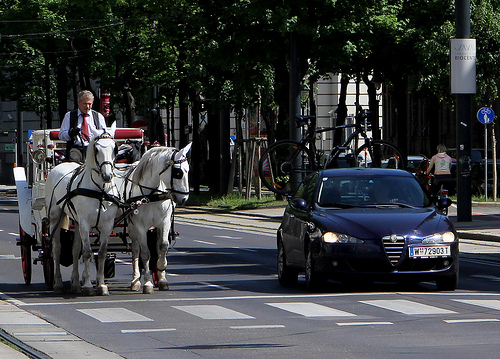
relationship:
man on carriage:
[59, 90, 110, 167] [18, 113, 152, 233]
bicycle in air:
[257, 101, 408, 197] [226, 148, 264, 235]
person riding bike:
[420, 145, 459, 199] [421, 172, 459, 214]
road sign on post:
[476, 113, 484, 124] [474, 105, 498, 202]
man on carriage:
[59, 90, 110, 167] [29, 128, 233, 295]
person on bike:
[420, 145, 453, 177] [415, 167, 475, 224]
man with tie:
[59, 90, 110, 167] [65, 107, 100, 137]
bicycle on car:
[252, 134, 373, 214] [295, 160, 458, 270]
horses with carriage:
[54, 142, 196, 234] [6, 120, 157, 226]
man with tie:
[59, 90, 110, 167] [77, 103, 105, 139]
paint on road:
[12, 283, 496, 355] [0, 192, 487, 356]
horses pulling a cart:
[42, 118, 122, 297] [34, 119, 194, 296]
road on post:
[0, 192, 487, 356] [474, 105, 497, 205]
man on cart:
[56, 80, 119, 167] [10, 114, 190, 292]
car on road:
[274, 163, 466, 286] [0, 192, 487, 356]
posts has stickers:
[442, 0, 476, 225] [445, 34, 478, 100]